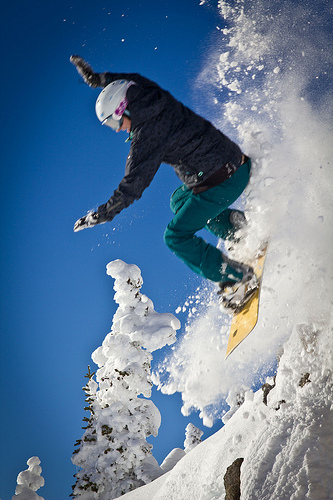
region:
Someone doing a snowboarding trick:
[53, 39, 260, 356]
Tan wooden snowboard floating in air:
[211, 215, 275, 356]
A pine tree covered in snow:
[61, 254, 176, 495]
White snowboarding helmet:
[89, 75, 136, 135]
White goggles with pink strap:
[97, 95, 131, 137]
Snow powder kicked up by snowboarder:
[151, 3, 326, 429]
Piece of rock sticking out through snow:
[220, 455, 251, 497]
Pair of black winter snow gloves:
[67, 47, 115, 235]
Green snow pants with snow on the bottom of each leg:
[160, 145, 255, 302]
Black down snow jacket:
[81, 61, 260, 227]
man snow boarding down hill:
[54, 28, 296, 351]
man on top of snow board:
[35, 34, 276, 328]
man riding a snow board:
[23, 21, 286, 380]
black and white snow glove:
[72, 207, 101, 233]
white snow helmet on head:
[95, 82, 127, 112]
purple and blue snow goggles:
[103, 102, 127, 131]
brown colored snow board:
[209, 306, 261, 361]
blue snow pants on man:
[160, 173, 247, 301]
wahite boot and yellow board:
[215, 250, 278, 343]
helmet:
[75, 79, 138, 137]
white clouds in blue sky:
[13, 238, 48, 278]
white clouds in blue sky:
[122, 212, 157, 255]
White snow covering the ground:
[125, 481, 175, 499]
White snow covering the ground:
[155, 456, 181, 478]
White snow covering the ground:
[168, 473, 187, 497]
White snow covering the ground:
[176, 457, 198, 489]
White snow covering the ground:
[205, 422, 233, 445]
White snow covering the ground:
[223, 453, 279, 489]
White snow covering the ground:
[270, 418, 305, 479]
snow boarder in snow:
[42, 46, 273, 361]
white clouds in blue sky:
[5, 22, 43, 79]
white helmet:
[86, 86, 122, 139]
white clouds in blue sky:
[4, 262, 44, 301]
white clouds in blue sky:
[33, 328, 63, 361]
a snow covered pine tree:
[66, 256, 183, 499]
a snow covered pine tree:
[11, 453, 47, 499]